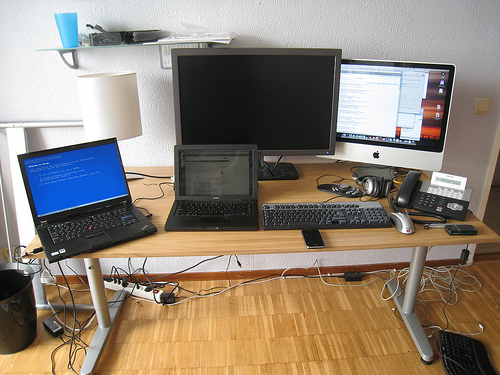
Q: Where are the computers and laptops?
A: On the desk.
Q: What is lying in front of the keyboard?
A: Cell phone.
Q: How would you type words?
A: With the keyboard.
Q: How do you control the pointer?
A: With the mouse.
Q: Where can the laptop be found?
A: On a desk.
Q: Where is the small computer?
A: On a desk.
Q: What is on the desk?
A: A lamp.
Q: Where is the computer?
A: On a desk.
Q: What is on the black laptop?
A: Blue screen.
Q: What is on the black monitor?
A: Black screen.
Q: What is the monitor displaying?
A: Programs.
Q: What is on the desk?
A: An assortment of computer monitors.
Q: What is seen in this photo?
A: A desk with 4 computers.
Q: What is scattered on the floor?
A: Wires.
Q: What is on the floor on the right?
A: Keyboard.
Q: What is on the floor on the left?
A: Garbage can.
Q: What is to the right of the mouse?
A: Phone.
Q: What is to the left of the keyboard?
A: Laptop.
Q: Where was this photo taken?
A: An office.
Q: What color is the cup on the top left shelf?
A: Blue.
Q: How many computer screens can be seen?
A: Four.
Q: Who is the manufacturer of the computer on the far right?
A: Apple.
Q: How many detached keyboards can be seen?
A: Two.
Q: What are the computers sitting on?
A: A desk.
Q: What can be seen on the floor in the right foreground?
A: A keyboard.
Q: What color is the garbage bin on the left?
A: Black.